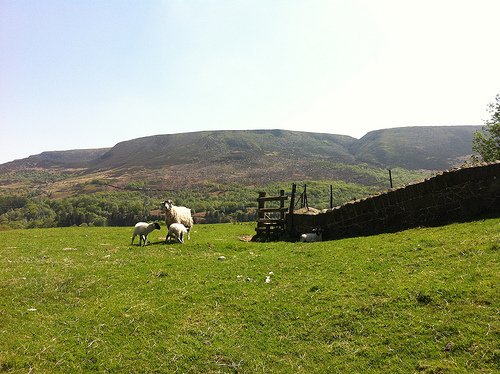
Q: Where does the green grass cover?
A: The field.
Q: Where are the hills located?
A: The background.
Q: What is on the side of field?
A: Fence.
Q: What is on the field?
A: Sheeps.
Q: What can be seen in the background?
A: Hills.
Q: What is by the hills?
A: Grass bushes.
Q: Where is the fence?
A: On the side.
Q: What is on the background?
A: Bushes.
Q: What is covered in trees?
A: Several mountains.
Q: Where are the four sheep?
A: In the field.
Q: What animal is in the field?
A: Sheep.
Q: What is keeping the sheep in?
A: Fence.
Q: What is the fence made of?
A: Stone.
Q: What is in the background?
A: Mountains.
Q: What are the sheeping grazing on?
A: Grass.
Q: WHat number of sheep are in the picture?
A: 3.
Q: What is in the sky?
A: Nothing.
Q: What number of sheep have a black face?
A: 1.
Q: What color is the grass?
A: Green.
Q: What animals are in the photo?
A: Sheep.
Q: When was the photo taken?
A: Daytime.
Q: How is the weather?
A: Sunny.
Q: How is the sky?
A: Has clouds.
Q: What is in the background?
A: A hill.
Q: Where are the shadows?
A: On the ground.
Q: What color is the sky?
A: Blue.